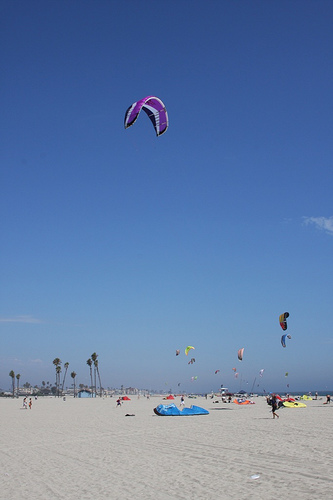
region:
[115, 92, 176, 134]
A purple para sail in the sky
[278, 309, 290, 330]
A red yellow and black para sail in the sky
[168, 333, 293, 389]
A large group of para sails in the sky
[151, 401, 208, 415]
A blue para sail on the beach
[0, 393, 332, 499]
A dry sandy beach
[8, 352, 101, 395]
some palm trees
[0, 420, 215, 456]
some tracks in the sand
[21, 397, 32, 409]
A pair of people on the beach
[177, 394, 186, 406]
A person walking on the beach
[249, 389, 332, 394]
The ocean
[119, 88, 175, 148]
purple black and white striped parachute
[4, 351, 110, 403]
a group of brown and green palm trees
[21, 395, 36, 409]
a group of people standing away from everything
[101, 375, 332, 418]
lots of people on the beach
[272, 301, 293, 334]
black yellow and red parachute in the air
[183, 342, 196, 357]
yellow parachute up in the air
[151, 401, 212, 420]
blue parachute laying down on the beach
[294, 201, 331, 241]
one white cloud in the blue sky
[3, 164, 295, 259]
blue sky with hardly and clouds in it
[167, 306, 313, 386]
a bunch of parachutes up in the air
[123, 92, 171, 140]
large purple kite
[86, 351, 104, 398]
cluster of three tall palm trees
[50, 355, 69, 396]
cluster of three tall palm trees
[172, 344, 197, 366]
three colorful kites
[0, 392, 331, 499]
a sandy beach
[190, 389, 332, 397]
dark blue ocean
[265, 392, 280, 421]
man flying a kite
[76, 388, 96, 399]
small, light blue hut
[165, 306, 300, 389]
several kits being flown over the beach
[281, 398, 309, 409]
yellow inflatable raft on the beach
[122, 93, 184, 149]
purple kite in sky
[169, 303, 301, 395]
many kites in background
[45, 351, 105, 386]
tall palm trees in background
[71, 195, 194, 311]
sky is blue and clear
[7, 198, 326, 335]
few thin clouds in sky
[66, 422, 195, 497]
white sand on beach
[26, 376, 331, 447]
many people on sand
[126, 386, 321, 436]
many kites on beach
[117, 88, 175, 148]
white stripe on purple kite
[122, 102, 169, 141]
black stripe on kite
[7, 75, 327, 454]
kites flying over a beach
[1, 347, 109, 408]
palm trees at edge of beach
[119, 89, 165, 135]
arched purple kite edged in black and white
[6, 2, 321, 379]
blue sky with a few faint white clouds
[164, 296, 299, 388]
curved kites flying close to each other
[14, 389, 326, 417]
beach goers on tan sand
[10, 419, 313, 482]
lines and footprints in sand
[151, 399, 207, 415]
blue kite with ruffled top on sand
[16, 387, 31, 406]
adult and child facing each other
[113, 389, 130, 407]
person running in front of red kite